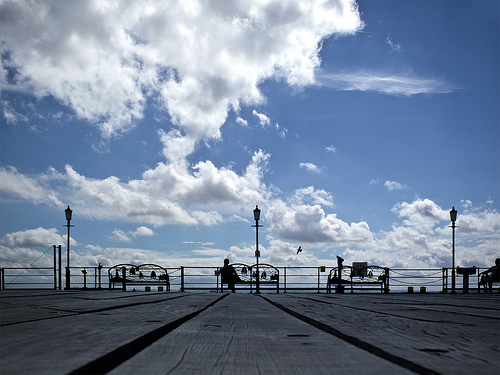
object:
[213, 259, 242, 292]
man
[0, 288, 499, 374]
floor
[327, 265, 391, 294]
benches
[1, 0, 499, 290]
sky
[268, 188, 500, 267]
clouds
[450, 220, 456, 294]
pole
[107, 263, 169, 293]
bench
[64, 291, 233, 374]
crack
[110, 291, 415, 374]
boards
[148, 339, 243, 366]
grains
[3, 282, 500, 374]
platform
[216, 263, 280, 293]
bench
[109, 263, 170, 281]
design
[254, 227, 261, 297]
pole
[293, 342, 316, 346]
hole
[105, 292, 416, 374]
plank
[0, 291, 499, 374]
pier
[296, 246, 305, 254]
birds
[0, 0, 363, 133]
cloud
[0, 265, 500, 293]
fence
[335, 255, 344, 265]
binoculars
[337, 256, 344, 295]
pole